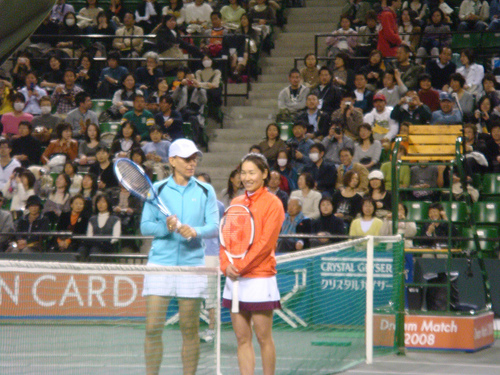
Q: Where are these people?
A: Tennis match.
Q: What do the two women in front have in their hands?
A: Tennis racquets.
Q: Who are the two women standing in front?
A: Tennis players.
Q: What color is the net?
A: White.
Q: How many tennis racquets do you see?
A: Two.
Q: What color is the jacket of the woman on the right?
A: Orange.